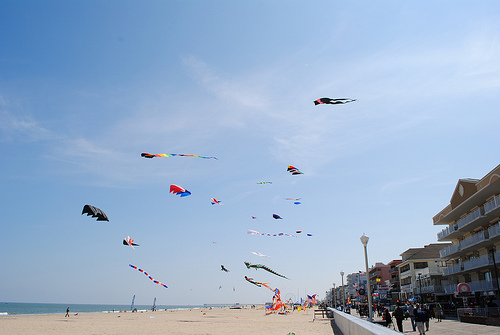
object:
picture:
[2, 0, 500, 335]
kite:
[129, 264, 169, 290]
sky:
[0, 0, 499, 303]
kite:
[243, 261, 291, 280]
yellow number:
[131, 307, 233, 334]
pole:
[357, 234, 374, 322]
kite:
[140, 152, 219, 160]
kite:
[286, 164, 304, 176]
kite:
[256, 181, 272, 185]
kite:
[169, 184, 192, 198]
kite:
[209, 197, 222, 206]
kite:
[285, 197, 302, 205]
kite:
[247, 229, 314, 238]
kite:
[244, 275, 275, 292]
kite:
[220, 264, 231, 273]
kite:
[122, 236, 140, 250]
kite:
[80, 204, 109, 223]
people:
[413, 305, 426, 334]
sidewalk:
[340, 302, 500, 334]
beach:
[198, 310, 298, 329]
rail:
[322, 303, 377, 335]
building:
[432, 168, 499, 330]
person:
[393, 304, 406, 332]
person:
[383, 308, 391, 326]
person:
[436, 303, 443, 323]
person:
[421, 303, 433, 332]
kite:
[313, 97, 359, 107]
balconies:
[431, 165, 500, 316]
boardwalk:
[331, 273, 447, 328]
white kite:
[251, 250, 270, 260]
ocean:
[0, 303, 244, 315]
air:
[150, 19, 377, 66]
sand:
[16, 308, 242, 334]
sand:
[216, 308, 238, 321]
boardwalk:
[334, 300, 499, 328]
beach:
[0, 306, 329, 335]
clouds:
[3, 64, 227, 182]